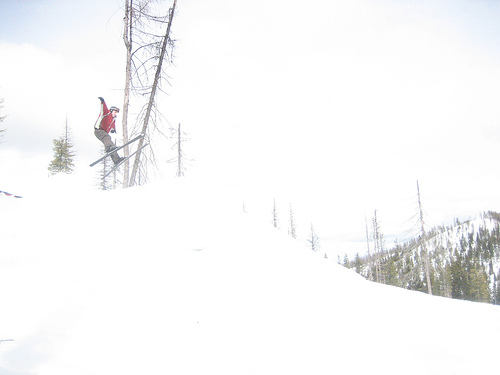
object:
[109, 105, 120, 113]
helmet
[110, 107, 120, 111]
goggles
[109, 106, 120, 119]
head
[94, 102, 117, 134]
coat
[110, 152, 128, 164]
boot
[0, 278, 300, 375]
ground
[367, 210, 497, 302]
trees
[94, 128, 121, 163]
pants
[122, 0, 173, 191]
tree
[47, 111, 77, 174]
tree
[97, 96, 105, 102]
glove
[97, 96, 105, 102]
hand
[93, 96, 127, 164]
man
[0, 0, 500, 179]
skies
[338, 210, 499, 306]
mountain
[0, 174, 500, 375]
snow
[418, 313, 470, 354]
white snow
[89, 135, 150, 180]
skis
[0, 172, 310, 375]
hill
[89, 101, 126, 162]
snowsuit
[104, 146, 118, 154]
feet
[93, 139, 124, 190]
tree